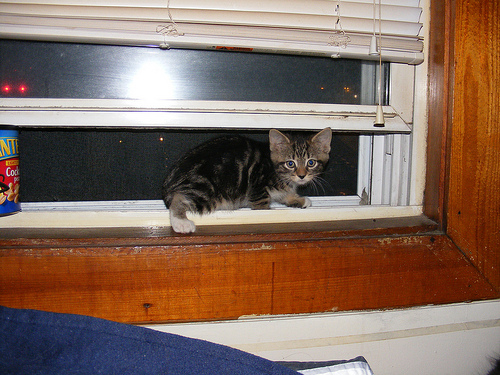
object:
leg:
[167, 190, 190, 222]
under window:
[0, 129, 427, 222]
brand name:
[0, 137, 21, 161]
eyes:
[306, 157, 319, 168]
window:
[0, 39, 429, 239]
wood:
[1, 1, 500, 328]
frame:
[0, 0, 499, 325]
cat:
[162, 127, 333, 234]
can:
[0, 129, 23, 216]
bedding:
[0, 304, 378, 375]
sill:
[0, 201, 455, 246]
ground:
[0, 295, 500, 375]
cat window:
[0, 195, 500, 324]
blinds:
[0, 0, 428, 65]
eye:
[285, 159, 296, 169]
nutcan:
[0, 128, 20, 217]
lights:
[0, 82, 30, 95]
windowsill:
[0, 194, 424, 227]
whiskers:
[273, 169, 331, 197]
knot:
[143, 302, 153, 308]